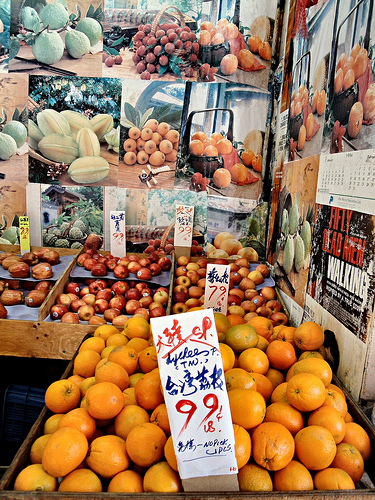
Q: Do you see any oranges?
A: Yes, there are oranges.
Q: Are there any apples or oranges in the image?
A: Yes, there are oranges.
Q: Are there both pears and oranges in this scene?
A: Yes, there are both oranges and a pear.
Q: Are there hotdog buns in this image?
A: No, there are no hotdog buns.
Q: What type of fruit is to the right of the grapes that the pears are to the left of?
A: The fruits are oranges.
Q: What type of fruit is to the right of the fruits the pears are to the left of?
A: The fruits are oranges.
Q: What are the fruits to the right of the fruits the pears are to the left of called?
A: The fruits are oranges.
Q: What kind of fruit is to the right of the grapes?
A: The fruits are oranges.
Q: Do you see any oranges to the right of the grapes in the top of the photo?
A: Yes, there are oranges to the right of the grapes.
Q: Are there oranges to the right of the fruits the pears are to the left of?
A: Yes, there are oranges to the right of the grapes.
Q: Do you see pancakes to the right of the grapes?
A: No, there are oranges to the right of the grapes.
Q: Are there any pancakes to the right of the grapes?
A: No, there are oranges to the right of the grapes.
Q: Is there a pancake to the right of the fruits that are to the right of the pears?
A: No, there are oranges to the right of the grapes.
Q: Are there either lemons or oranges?
A: Yes, there are oranges.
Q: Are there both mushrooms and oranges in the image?
A: No, there are oranges but no mushrooms.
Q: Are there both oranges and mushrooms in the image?
A: No, there are oranges but no mushrooms.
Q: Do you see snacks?
A: No, there are no snacks.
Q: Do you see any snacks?
A: No, there are no snacks.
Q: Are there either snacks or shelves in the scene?
A: No, there are no snacks or shelves.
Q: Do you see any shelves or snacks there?
A: No, there are no snacks or shelves.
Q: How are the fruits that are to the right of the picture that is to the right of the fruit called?
A: The fruits are oranges.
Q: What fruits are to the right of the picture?
A: The fruits are oranges.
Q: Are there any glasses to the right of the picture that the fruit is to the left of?
A: No, there are oranges to the right of the picture.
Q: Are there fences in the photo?
A: No, there are no fences.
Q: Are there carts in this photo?
A: No, there are no carts.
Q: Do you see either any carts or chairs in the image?
A: No, there are no carts or chairs.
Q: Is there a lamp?
A: No, there are no lamps.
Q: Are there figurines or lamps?
A: No, there are no lamps or figurines.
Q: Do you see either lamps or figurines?
A: No, there are no lamps or figurines.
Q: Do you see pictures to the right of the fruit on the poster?
A: Yes, there is a picture to the right of the fruit.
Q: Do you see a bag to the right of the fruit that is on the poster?
A: No, there is a picture to the right of the fruit.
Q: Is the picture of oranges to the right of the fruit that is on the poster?
A: Yes, the picture is to the right of the fruit.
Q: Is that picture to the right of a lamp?
A: No, the picture is to the right of the fruit.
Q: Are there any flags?
A: No, there are no flags.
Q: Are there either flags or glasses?
A: No, there are no flags or glasses.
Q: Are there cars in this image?
A: No, there are no cars.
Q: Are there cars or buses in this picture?
A: No, there are no cars or buses.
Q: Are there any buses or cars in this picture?
A: No, there are no cars or buses.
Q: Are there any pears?
A: Yes, there are pears.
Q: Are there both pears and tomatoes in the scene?
A: No, there are pears but no tomatoes.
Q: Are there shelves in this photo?
A: No, there are no shelves.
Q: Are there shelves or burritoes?
A: No, there are no shelves or burritoes.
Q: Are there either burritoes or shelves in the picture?
A: No, there are no shelves or burritoes.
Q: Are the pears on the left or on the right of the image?
A: The pears are on the left of the image.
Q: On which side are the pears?
A: The pears are on the left of the image.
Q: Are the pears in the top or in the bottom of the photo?
A: The pears are in the top of the image.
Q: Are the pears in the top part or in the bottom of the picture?
A: The pears are in the top of the image.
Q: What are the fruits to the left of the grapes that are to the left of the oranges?
A: The fruits are pears.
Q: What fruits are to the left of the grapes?
A: The fruits are pears.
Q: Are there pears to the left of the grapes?
A: Yes, there are pears to the left of the grapes.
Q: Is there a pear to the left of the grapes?
A: Yes, there are pears to the left of the grapes.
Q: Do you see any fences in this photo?
A: No, there are no fences.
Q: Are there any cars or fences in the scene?
A: No, there are no fences or cars.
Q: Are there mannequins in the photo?
A: No, there are no mannequins.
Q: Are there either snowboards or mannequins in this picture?
A: No, there are no mannequins or snowboards.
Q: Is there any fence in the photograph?
A: No, there are no fences.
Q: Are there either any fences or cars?
A: No, there are no fences or cars.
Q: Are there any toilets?
A: No, there are no toilets.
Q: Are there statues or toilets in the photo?
A: No, there are no toilets or statues.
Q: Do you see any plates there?
A: No, there are no plates.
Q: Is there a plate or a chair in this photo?
A: No, there are no plates or chairs.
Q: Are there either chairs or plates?
A: No, there are no plates or chairs.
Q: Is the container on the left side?
A: Yes, the container is on the left of the image.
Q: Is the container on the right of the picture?
A: No, the container is on the left of the image.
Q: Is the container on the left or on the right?
A: The container is on the left of the image.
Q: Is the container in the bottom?
A: Yes, the container is in the bottom of the image.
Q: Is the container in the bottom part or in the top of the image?
A: The container is in the bottom of the image.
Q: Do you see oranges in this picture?
A: Yes, there are oranges.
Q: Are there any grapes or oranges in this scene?
A: Yes, there are oranges.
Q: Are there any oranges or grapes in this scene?
A: Yes, there are oranges.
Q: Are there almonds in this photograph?
A: No, there are no almonds.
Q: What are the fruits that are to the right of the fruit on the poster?
A: The fruits are oranges.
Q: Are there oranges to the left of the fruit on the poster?
A: No, the oranges are to the right of the fruit.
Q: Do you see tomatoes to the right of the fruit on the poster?
A: No, there are oranges to the right of the fruit.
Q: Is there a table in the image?
A: Yes, there is a table.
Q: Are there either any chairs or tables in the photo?
A: Yes, there is a table.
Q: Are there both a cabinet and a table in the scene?
A: No, there is a table but no cabinets.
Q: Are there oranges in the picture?
A: Yes, there are oranges.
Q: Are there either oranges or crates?
A: Yes, there are oranges.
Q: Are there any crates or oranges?
A: Yes, there are oranges.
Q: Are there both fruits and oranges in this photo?
A: Yes, there are both oranges and fruits.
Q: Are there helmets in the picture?
A: No, there are no helmets.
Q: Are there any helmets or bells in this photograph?
A: No, there are no helmets or bells.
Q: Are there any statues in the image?
A: No, there are no statues.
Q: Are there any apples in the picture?
A: Yes, there are apples.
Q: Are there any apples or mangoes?
A: Yes, there are apples.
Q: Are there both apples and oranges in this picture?
A: Yes, there are both apples and oranges.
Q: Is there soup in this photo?
A: No, there is no soup.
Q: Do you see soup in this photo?
A: No, there is no soup.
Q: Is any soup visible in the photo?
A: No, there is no soup.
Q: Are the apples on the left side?
A: Yes, the apples are on the left of the image.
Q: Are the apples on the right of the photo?
A: No, the apples are on the left of the image.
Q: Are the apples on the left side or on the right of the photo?
A: The apples are on the left of the image.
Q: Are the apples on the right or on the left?
A: The apples are on the left of the image.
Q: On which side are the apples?
A: The apples are on the left of the image.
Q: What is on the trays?
A: The apples are on the trays.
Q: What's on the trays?
A: The apples are on the trays.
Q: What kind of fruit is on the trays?
A: The fruits are apples.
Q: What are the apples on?
A: The apples are on the trays.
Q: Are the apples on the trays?
A: Yes, the apples are on the trays.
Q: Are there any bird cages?
A: No, there are no bird cages.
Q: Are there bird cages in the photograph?
A: No, there are no bird cages.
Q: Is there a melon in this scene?
A: Yes, there are melons.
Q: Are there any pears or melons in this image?
A: Yes, there are melons.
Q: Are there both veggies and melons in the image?
A: No, there are melons but no vegetables.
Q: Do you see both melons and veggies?
A: No, there are melons but no vegetables.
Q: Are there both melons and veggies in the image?
A: No, there are melons but no vegetables.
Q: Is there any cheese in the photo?
A: No, there is no cheese.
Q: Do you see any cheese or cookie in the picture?
A: No, there are no cheese or cookies.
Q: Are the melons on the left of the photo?
A: Yes, the melons are on the left of the image.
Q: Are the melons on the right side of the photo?
A: No, the melons are on the left of the image.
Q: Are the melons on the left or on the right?
A: The melons are on the left of the image.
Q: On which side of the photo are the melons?
A: The melons are on the left of the image.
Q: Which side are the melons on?
A: The melons are on the left of the image.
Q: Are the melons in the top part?
A: Yes, the melons are in the top of the image.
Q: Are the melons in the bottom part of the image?
A: No, the melons are in the top of the image.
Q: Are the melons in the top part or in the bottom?
A: The melons are in the top of the image.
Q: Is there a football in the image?
A: No, there are no footballs.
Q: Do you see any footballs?
A: No, there are no footballs.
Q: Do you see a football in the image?
A: No, there are no footballs.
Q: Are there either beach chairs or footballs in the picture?
A: No, there are no footballs or beach chairs.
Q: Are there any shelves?
A: No, there are no shelves.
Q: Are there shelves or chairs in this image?
A: No, there are no shelves or chairs.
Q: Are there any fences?
A: No, there are no fences.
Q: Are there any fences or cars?
A: No, there are no fences or cars.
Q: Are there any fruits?
A: Yes, there is a fruit.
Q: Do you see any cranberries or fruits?
A: Yes, there is a fruit.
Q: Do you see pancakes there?
A: No, there are no pancakes.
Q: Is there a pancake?
A: No, there are no pancakes.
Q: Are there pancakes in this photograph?
A: No, there are no pancakes.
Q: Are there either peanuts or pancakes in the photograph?
A: No, there are no pancakes or peanuts.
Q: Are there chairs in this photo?
A: No, there are no chairs.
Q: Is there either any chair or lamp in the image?
A: No, there are no chairs or lamps.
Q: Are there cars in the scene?
A: No, there are no cars.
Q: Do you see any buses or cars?
A: No, there are no cars or buses.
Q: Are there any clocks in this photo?
A: No, there are no clocks.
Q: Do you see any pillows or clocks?
A: No, there are no clocks or pillows.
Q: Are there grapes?
A: Yes, there are grapes.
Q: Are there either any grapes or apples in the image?
A: Yes, there are grapes.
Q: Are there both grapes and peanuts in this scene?
A: No, there are grapes but no peanuts.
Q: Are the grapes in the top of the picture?
A: Yes, the grapes are in the top of the image.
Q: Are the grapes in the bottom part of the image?
A: No, the grapes are in the top of the image.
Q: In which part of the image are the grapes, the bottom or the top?
A: The grapes are in the top of the image.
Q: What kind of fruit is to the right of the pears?
A: The fruits are grapes.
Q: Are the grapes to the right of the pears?
A: Yes, the grapes are to the right of the pears.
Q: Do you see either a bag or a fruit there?
A: Yes, there is a fruit.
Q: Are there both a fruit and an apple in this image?
A: Yes, there are both a fruit and an apple.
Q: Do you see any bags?
A: No, there are no bags.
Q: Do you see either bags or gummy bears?
A: No, there are no bags or gummy bears.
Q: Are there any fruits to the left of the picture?
A: Yes, there is a fruit to the left of the picture.